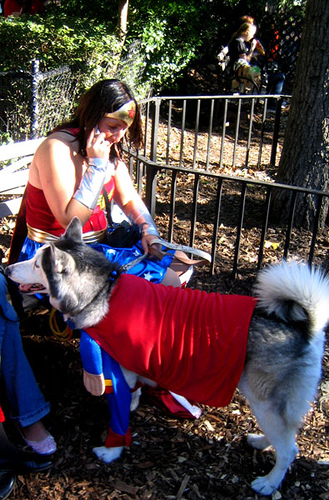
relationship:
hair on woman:
[44, 72, 146, 154] [38, 78, 211, 416]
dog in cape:
[2, 212, 328, 499] [77, 272, 259, 447]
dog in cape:
[2, 212, 328, 499] [86, 270, 258, 409]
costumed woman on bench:
[14, 78, 193, 292] [4, 138, 62, 320]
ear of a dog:
[48, 241, 74, 272] [22, 230, 317, 347]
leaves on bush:
[147, 25, 162, 39] [138, 10, 201, 64]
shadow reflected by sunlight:
[152, 190, 267, 227] [178, 127, 280, 170]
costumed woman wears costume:
[14, 78, 193, 292] [16, 145, 194, 284]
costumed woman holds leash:
[26, 77, 172, 253] [116, 252, 144, 273]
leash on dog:
[116, 252, 144, 273] [5, 231, 316, 464]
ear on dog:
[61, 215, 83, 245] [2, 212, 328, 499]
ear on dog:
[36, 236, 55, 267] [2, 212, 328, 499]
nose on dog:
[1, 263, 12, 275] [2, 212, 328, 499]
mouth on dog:
[8, 275, 46, 295] [2, 212, 328, 499]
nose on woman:
[112, 130, 123, 141] [22, 78, 159, 278]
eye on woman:
[108, 124, 116, 130] [8, 77, 180, 331]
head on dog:
[3, 215, 113, 316] [2, 212, 328, 499]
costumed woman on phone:
[14, 78, 193, 292] [84, 124, 99, 138]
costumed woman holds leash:
[14, 78, 193, 292] [117, 238, 211, 272]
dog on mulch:
[3, 214, 329, 496] [173, 457, 234, 498]